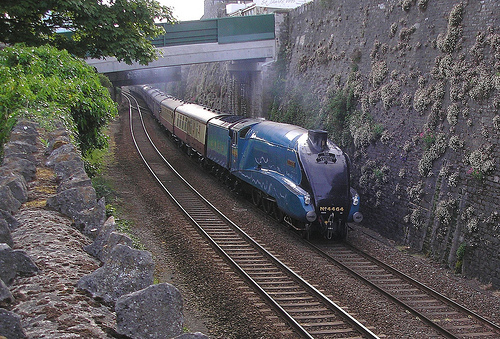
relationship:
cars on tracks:
[127, 83, 365, 242] [232, 234, 437, 325]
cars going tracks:
[127, 83, 365, 242] [233, 243, 368, 330]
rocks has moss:
[262, 0, 499, 281] [408, 66, 445, 116]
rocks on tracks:
[323, 50, 459, 197] [173, 170, 284, 287]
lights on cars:
[314, 182, 366, 218] [127, 83, 365, 242]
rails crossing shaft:
[113, 82, 498, 339] [248, 118, 359, 232]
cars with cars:
[127, 83, 365, 242] [138, 70, 210, 149]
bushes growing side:
[0, 0, 179, 160] [20, 106, 187, 289]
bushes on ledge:
[4, 1, 126, 161] [14, 100, 147, 304]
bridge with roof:
[66, 16, 301, 90] [120, 9, 267, 42]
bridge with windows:
[66, 16, 301, 90] [59, 34, 119, 63]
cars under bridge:
[127, 83, 365, 242] [42, 10, 288, 72]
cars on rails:
[127, 83, 365, 242] [113, 82, 498, 339]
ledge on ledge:
[2, 114, 187, 337] [2, 100, 212, 336]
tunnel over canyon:
[57, 13, 287, 83] [0, 0, 499, 339]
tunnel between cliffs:
[76, 57, 282, 164] [2, 0, 499, 336]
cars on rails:
[127, 83, 365, 242] [123, 83, 499, 335]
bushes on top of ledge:
[0, 0, 179, 160] [0, 40, 204, 335]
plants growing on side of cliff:
[159, 1, 499, 290] [152, 0, 499, 282]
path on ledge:
[9, 123, 115, 336] [2, 100, 212, 336]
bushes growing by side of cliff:
[0, 0, 179, 160] [3, 42, 213, 336]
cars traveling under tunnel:
[127, 83, 365, 242] [9, 11, 287, 72]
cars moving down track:
[127, 83, 365, 242] [121, 85, 499, 335]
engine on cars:
[204, 112, 363, 240] [127, 83, 365, 242]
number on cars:
[316, 203, 346, 213] [127, 83, 365, 242]